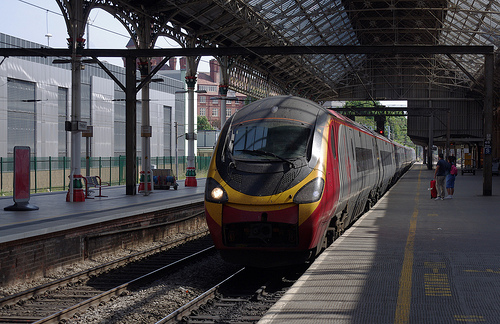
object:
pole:
[65, 26, 84, 203]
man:
[433, 153, 448, 201]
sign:
[4, 144, 47, 212]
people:
[443, 158, 458, 200]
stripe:
[385, 166, 425, 322]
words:
[422, 249, 453, 300]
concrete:
[260, 160, 499, 324]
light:
[292, 176, 322, 203]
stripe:
[390, 162, 422, 322]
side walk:
[252, 160, 496, 322]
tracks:
[3, 210, 296, 321]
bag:
[430, 180, 438, 199]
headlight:
[203, 177, 227, 205]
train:
[203, 97, 416, 264]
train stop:
[4, 0, 494, 320]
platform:
[1, 178, 208, 243]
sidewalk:
[264, 162, 498, 322]